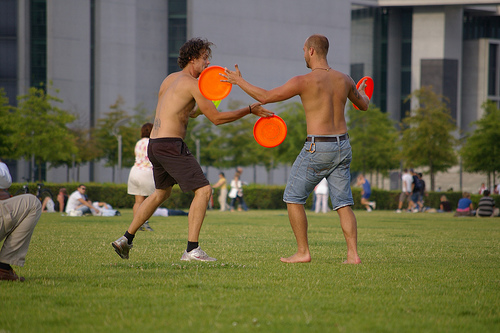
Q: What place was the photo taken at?
A: It was taken at the field.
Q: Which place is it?
A: It is a field.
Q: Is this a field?
A: Yes, it is a field.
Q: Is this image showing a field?
A: Yes, it is showing a field.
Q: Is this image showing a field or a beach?
A: It is showing a field.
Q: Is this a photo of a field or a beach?
A: It is showing a field.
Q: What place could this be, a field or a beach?
A: It is a field.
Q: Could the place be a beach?
A: No, it is a field.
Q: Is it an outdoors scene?
A: Yes, it is outdoors.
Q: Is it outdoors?
A: Yes, it is outdoors.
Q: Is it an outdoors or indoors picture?
A: It is outdoors.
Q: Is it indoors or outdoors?
A: It is outdoors.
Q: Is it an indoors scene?
A: No, it is outdoors.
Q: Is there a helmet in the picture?
A: No, there are no helmets.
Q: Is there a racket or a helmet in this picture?
A: No, there are no helmets or rackets.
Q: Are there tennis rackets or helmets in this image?
A: No, there are no helmets or tennis rackets.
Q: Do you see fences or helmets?
A: No, there are no fences or helmets.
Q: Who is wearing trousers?
A: The man is wearing trousers.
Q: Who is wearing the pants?
A: The man is wearing trousers.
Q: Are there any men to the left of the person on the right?
A: Yes, there is a man to the left of the person.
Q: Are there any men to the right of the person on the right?
A: No, the man is to the left of the person.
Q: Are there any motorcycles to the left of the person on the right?
A: No, there is a man to the left of the person.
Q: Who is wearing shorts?
A: The man is wearing shorts.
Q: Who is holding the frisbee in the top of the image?
A: The man is holding the frisbee.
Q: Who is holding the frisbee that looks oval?
A: The man is holding the frisbee.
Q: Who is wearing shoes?
A: The man is wearing shoes.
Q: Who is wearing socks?
A: The man is wearing socks.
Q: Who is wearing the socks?
A: The man is wearing socks.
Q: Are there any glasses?
A: No, there are no glasses.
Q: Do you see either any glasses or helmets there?
A: No, there are no glasses or helmets.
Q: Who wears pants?
A: The man wears pants.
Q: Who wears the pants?
A: The man wears pants.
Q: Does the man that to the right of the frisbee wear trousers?
A: Yes, the man wears trousers.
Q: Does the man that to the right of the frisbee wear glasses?
A: No, the man wears trousers.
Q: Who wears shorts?
A: The man wears shorts.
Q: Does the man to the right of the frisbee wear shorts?
A: Yes, the man wears shorts.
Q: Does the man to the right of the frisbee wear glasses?
A: No, the man wears shorts.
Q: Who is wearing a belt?
A: The man is wearing a belt.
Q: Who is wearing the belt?
A: The man is wearing a belt.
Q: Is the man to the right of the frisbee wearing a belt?
A: Yes, the man is wearing a belt.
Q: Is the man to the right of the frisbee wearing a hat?
A: No, the man is wearing a belt.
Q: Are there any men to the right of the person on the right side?
A: No, the man is to the left of the person.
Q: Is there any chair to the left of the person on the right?
A: No, there is a man to the left of the person.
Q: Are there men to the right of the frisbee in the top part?
A: Yes, there is a man to the right of the frisbee.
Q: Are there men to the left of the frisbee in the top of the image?
A: No, the man is to the right of the frisbee.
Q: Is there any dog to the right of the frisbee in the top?
A: No, there is a man to the right of the frisbee.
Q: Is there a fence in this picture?
A: No, there are no fences.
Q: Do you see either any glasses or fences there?
A: No, there are no fences or glasses.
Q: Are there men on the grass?
A: Yes, there is a man on the grass.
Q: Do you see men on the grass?
A: Yes, there is a man on the grass.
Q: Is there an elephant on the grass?
A: No, there is a man on the grass.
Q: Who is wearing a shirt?
A: The man is wearing a shirt.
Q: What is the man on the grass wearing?
A: The man is wearing a shirt.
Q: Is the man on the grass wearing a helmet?
A: No, the man is wearing a shirt.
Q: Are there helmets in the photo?
A: No, there are no helmets.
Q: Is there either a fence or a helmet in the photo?
A: No, there are no helmets or fences.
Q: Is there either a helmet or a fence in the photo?
A: No, there are no helmets or fences.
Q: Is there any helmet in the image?
A: No, there are no helmets.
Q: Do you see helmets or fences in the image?
A: No, there are no helmets or fences.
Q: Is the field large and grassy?
A: Yes, the field is large and grassy.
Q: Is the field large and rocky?
A: No, the field is large but grassy.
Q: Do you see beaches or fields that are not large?
A: No, there is a field but it is large.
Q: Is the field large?
A: Yes, the field is large.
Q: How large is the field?
A: The field is large.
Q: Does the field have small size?
A: No, the field is large.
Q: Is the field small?
A: No, the field is large.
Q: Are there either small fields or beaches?
A: No, there is a field but it is large.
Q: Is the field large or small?
A: The field is large.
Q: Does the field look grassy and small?
A: No, the field is grassy but large.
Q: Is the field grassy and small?
A: No, the field is grassy but large.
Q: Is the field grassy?
A: Yes, the field is grassy.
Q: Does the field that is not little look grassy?
A: Yes, the field is grassy.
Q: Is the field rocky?
A: No, the field is grassy.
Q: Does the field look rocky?
A: No, the field is grassy.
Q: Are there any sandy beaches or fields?
A: No, there is a field but it is grassy.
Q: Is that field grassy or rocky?
A: The field is grassy.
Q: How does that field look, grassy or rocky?
A: The field is grassy.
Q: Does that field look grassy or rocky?
A: The field is grassy.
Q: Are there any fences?
A: No, there are no fences.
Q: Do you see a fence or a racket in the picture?
A: No, there are no fences or rackets.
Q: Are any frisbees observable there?
A: Yes, there is a frisbee.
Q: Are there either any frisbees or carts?
A: Yes, there is a frisbee.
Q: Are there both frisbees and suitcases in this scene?
A: No, there is a frisbee but no suitcases.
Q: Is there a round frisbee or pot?
A: Yes, there is a round frisbee.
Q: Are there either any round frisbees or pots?
A: Yes, there is a round frisbee.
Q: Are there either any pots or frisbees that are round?
A: Yes, the frisbee is round.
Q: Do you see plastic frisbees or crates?
A: Yes, there is a plastic frisbee.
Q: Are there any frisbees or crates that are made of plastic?
A: Yes, the frisbee is made of plastic.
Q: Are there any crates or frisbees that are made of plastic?
A: Yes, the frisbee is made of plastic.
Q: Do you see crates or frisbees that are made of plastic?
A: Yes, the frisbee is made of plastic.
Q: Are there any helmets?
A: No, there are no helmets.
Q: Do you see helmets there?
A: No, there are no helmets.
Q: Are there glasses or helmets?
A: No, there are no helmets or glasses.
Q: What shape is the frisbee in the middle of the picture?
A: The frisbee is round.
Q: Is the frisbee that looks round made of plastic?
A: Yes, the frisbee is made of plastic.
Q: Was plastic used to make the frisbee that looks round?
A: Yes, the frisbee is made of plastic.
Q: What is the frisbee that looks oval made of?
A: The frisbee is made of plastic.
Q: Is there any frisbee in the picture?
A: Yes, there is a frisbee.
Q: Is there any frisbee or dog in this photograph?
A: Yes, there is a frisbee.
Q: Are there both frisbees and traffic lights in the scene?
A: No, there is a frisbee but no traffic lights.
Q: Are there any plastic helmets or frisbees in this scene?
A: Yes, there is a plastic frisbee.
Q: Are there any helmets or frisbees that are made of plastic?
A: Yes, the frisbee is made of plastic.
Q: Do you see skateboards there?
A: No, there are no skateboards.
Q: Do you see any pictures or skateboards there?
A: No, there are no skateboards or pictures.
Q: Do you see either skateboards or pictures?
A: No, there are no skateboards or pictures.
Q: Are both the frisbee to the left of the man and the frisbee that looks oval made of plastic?
A: Yes, both the frisbee and the frisbee are made of plastic.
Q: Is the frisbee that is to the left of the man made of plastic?
A: Yes, the frisbee is made of plastic.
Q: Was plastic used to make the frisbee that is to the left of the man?
A: Yes, the frisbee is made of plastic.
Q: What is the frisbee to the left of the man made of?
A: The frisbee is made of plastic.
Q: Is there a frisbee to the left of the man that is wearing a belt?
A: Yes, there is a frisbee to the left of the man.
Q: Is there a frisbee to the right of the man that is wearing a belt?
A: No, the frisbee is to the left of the man.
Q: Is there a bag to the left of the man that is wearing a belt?
A: No, there is a frisbee to the left of the man.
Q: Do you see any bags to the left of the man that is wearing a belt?
A: No, there is a frisbee to the left of the man.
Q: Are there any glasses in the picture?
A: No, there are no glasses.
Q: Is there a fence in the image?
A: No, there are no fences.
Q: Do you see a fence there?
A: No, there are no fences.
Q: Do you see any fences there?
A: No, there are no fences.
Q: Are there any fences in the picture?
A: No, there are no fences.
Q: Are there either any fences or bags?
A: No, there are no fences or bags.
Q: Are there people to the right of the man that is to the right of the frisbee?
A: Yes, there is a person to the right of the man.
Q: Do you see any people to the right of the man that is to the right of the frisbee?
A: Yes, there is a person to the right of the man.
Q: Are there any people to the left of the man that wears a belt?
A: No, the person is to the right of the man.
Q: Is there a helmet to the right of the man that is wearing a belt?
A: No, there is a person to the right of the man.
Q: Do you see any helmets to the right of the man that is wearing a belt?
A: No, there is a person to the right of the man.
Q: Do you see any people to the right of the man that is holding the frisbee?
A: Yes, there is a person to the right of the man.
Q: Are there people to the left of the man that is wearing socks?
A: No, the person is to the right of the man.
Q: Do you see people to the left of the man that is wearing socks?
A: No, the person is to the right of the man.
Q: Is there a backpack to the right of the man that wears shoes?
A: No, there is a person to the right of the man.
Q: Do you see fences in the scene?
A: No, there are no fences.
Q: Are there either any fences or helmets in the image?
A: No, there are no fences or helmets.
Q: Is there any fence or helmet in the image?
A: No, there are no fences or helmets.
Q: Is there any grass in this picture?
A: Yes, there is grass.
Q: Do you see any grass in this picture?
A: Yes, there is grass.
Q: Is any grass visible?
A: Yes, there is grass.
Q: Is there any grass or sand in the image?
A: Yes, there is grass.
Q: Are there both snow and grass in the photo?
A: No, there is grass but no snow.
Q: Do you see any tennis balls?
A: No, there are no tennis balls.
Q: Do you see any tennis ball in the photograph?
A: No, there are no tennis balls.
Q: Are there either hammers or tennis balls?
A: No, there are no tennis balls or hammers.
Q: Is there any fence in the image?
A: No, there are no fences.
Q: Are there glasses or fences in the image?
A: No, there are no fences or glasses.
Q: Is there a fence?
A: No, there are no fences.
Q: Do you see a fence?
A: No, there are no fences.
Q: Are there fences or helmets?
A: No, there are no fences or helmets.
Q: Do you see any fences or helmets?
A: No, there are no fences or helmets.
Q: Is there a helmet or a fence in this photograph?
A: No, there are no fences or helmets.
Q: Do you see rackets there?
A: No, there are no rackets.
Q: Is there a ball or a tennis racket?
A: No, there are no rackets or balls.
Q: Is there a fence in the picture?
A: No, there are no fences.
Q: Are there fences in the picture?
A: No, there are no fences.